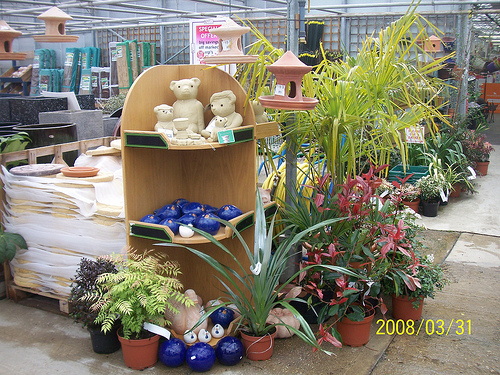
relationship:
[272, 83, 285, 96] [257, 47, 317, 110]
price tag on bird feeder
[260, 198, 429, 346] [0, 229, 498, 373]
plants on ground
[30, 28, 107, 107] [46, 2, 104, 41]
feeder on display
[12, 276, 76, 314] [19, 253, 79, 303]
pallet supporting pottery